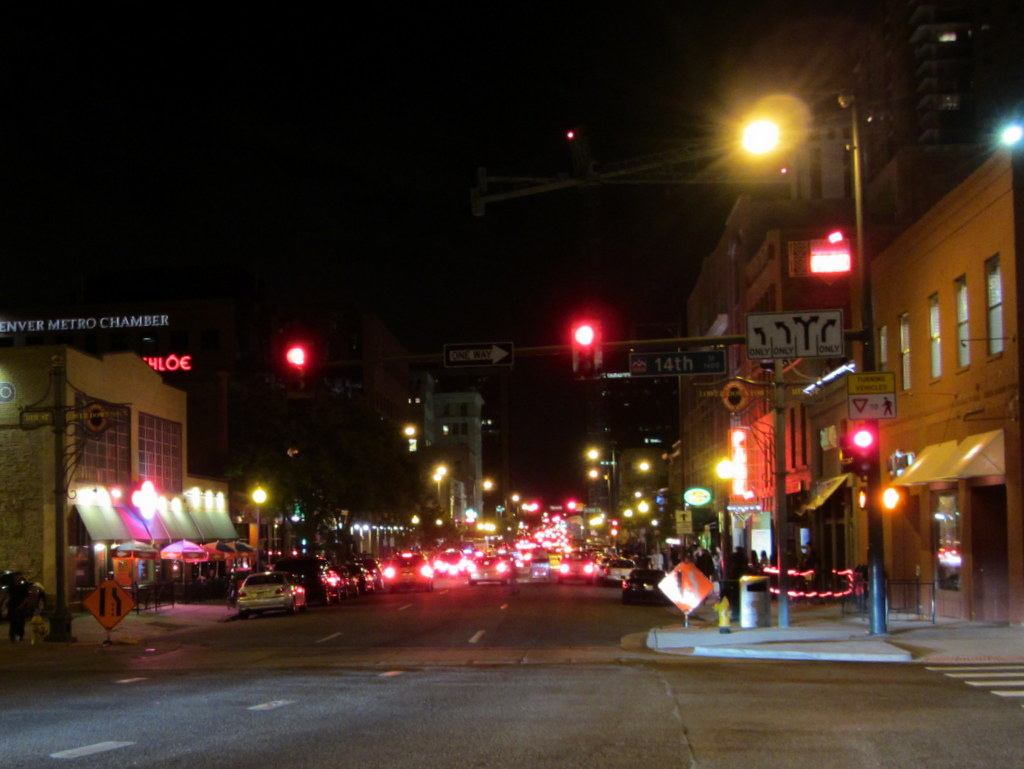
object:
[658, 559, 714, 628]
sign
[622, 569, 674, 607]
car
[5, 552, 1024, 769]
road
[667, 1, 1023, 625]
building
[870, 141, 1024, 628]
wall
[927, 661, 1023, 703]
crosswalk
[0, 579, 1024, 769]
intersection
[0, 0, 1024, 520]
sky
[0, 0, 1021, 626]
buildings